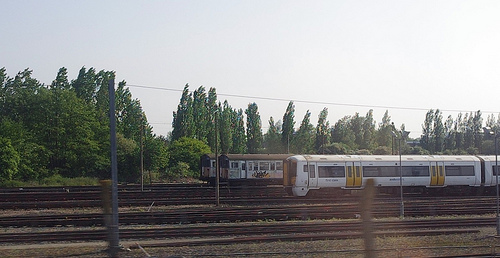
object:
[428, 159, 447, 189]
yellow doors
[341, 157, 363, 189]
yellow doors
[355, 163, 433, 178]
window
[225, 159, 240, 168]
window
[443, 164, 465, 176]
passenger window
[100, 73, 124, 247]
pole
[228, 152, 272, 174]
wall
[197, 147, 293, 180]
building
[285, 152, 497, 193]
train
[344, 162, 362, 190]
doors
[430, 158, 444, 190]
door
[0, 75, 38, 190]
trees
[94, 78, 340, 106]
power lines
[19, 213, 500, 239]
tracks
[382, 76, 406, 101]
sky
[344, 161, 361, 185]
train doors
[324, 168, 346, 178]
window